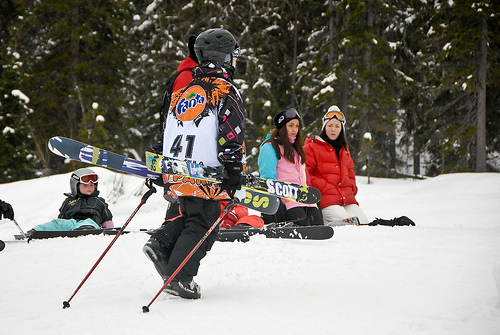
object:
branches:
[1, 44, 499, 176]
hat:
[321, 104, 347, 131]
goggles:
[324, 110, 346, 121]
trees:
[5, 0, 500, 181]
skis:
[47, 135, 321, 214]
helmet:
[194, 28, 240, 64]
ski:
[211, 217, 335, 243]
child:
[146, 30, 246, 302]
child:
[257, 107, 324, 226]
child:
[305, 105, 370, 225]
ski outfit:
[29, 195, 114, 233]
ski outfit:
[148, 63, 245, 281]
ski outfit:
[257, 134, 325, 226]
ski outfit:
[300, 134, 371, 225]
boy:
[21, 167, 115, 238]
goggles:
[79, 173, 100, 184]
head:
[194, 27, 242, 72]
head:
[273, 108, 301, 139]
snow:
[11, 175, 492, 333]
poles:
[61, 180, 238, 314]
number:
[169, 134, 196, 158]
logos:
[175, 85, 207, 122]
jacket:
[150, 68, 251, 209]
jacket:
[257, 134, 319, 211]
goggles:
[224, 45, 242, 62]